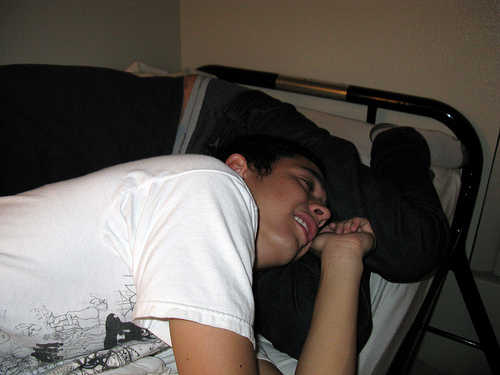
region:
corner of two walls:
[0, 2, 498, 70]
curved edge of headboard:
[210, 66, 485, 201]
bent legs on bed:
[3, 63, 453, 362]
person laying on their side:
[1, 144, 373, 373]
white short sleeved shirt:
[2, 154, 255, 373]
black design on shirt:
[2, 294, 174, 373]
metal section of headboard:
[271, 72, 353, 104]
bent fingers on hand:
[314, 216, 375, 248]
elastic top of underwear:
[171, 75, 210, 155]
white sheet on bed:
[260, 112, 462, 374]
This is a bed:
[62, 98, 307, 353]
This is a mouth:
[255, 196, 369, 283]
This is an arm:
[132, 214, 237, 374]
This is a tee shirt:
[154, 206, 204, 308]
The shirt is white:
[58, 217, 191, 366]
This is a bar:
[285, 89, 464, 193]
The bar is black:
[427, 116, 489, 143]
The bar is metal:
[446, 109, 480, 208]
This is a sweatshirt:
[391, 153, 420, 260]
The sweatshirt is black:
[348, 246, 425, 251]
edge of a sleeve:
[204, 320, 219, 332]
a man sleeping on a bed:
[1, 134, 377, 373]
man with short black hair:
[197, 128, 332, 268]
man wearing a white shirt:
[1, 153, 258, 372]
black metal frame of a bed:
[198, 62, 498, 374]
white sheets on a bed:
[255, 263, 439, 373]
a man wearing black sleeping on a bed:
[3, 57, 455, 366]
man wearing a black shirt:
[1, 61, 185, 193]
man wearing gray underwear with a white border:
[176, 69, 246, 156]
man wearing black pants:
[208, 90, 452, 365]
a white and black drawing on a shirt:
[6, 275, 170, 372]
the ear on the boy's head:
[225, 152, 245, 179]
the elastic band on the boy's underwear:
[173, 75, 212, 159]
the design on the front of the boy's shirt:
[0, 270, 170, 374]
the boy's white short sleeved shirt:
[0, 153, 275, 374]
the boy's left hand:
[310, 214, 377, 252]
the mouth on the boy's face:
[291, 209, 318, 245]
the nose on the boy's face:
[307, 202, 329, 228]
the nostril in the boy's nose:
[312, 207, 323, 216]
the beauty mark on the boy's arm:
[238, 363, 242, 368]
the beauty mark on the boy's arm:
[185, 357, 188, 362]